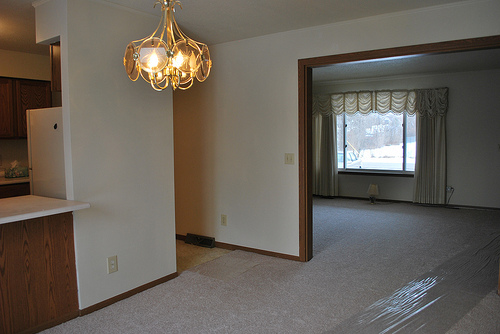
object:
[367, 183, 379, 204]
lamp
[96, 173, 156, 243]
wall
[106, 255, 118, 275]
outlet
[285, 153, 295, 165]
light switch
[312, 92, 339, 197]
curtain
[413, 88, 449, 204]
curtain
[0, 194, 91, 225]
counter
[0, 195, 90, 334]
frame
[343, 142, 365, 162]
shrubs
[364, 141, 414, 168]
grass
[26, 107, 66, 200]
side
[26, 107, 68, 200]
fridge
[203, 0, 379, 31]
ceiling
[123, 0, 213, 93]
chandelier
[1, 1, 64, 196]
kitchen area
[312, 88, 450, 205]
curtain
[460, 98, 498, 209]
wall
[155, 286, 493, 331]
floor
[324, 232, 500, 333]
cover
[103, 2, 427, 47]
roof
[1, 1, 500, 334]
interior_of_house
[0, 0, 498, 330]
dining area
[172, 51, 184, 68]
light bulbs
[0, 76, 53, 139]
cabinets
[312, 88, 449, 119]
valance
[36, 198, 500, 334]
carpet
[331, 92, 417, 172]
window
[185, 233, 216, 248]
object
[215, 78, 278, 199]
wall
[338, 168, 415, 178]
shelf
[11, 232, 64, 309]
wood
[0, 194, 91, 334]
bar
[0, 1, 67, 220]
kitchen